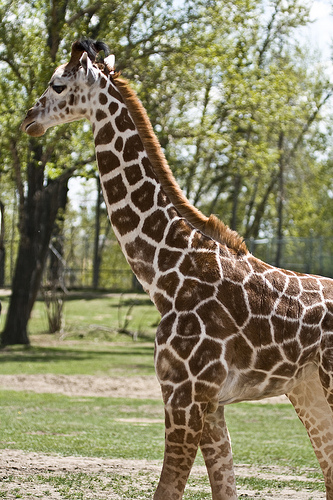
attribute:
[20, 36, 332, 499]
giraffe — brown, spotted, white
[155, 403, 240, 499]
legs — apart, long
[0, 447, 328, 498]
road — dirt, brown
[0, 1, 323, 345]
tree — green, tall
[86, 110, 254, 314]
neck — long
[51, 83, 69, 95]
eye — black, open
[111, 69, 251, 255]
mane — thick, brown, short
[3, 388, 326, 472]
grass — green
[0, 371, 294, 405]
ground — dirt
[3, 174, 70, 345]
trunk — tree trunk, black, brown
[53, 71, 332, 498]
spots — brown, white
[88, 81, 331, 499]
fur — black, brown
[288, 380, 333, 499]
back leg — spotted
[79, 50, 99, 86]
ear — pointy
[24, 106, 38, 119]
snout — brown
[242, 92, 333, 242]
tree trunk — brown, thin